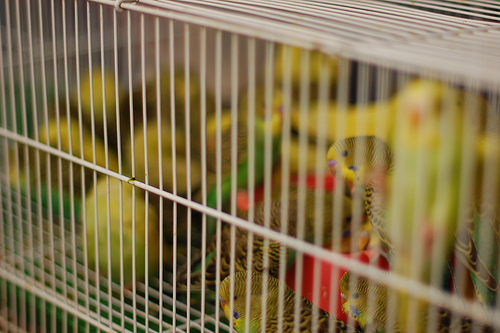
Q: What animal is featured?
A: Birds.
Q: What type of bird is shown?
A: Parakeets.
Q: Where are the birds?
A: In a cage.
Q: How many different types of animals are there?
A: One.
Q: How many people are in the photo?
A: None.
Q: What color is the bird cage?
A: White.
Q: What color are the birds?
A: Yellow and green.